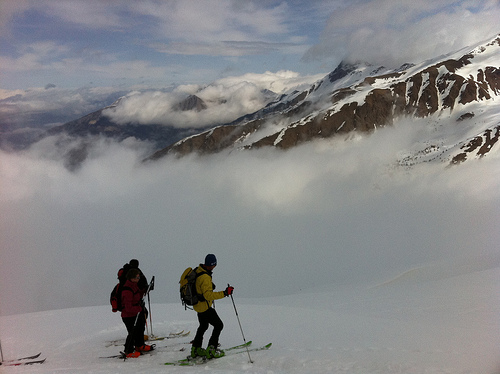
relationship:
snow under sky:
[9, 303, 484, 366] [3, 3, 479, 151]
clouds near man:
[7, 145, 499, 289] [172, 250, 261, 367]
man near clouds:
[172, 250, 261, 367] [7, 145, 499, 289]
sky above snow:
[3, 3, 479, 151] [9, 303, 484, 366]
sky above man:
[3, 3, 479, 151] [172, 250, 261, 367]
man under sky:
[172, 250, 261, 367] [3, 3, 479, 151]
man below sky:
[172, 250, 261, 367] [3, 3, 479, 151]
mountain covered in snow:
[76, 34, 459, 196] [9, 303, 484, 366]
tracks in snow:
[281, 341, 371, 371] [9, 303, 484, 366]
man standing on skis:
[178, 252, 233, 357] [164, 338, 273, 364]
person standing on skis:
[110, 268, 153, 348] [107, 341, 216, 365]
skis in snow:
[173, 340, 275, 367] [3, 303, 475, 371]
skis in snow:
[104, 335, 205, 356] [9, 303, 484, 366]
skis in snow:
[105, 329, 187, 348] [9, 303, 484, 366]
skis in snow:
[3, 346, 44, 368] [19, 300, 446, 371]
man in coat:
[178, 252, 233, 357] [179, 270, 230, 314]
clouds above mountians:
[7, 145, 499, 289] [128, 48, 481, 165]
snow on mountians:
[215, 74, 385, 144] [134, 50, 484, 180]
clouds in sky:
[7, 145, 499, 289] [16, 6, 477, 140]